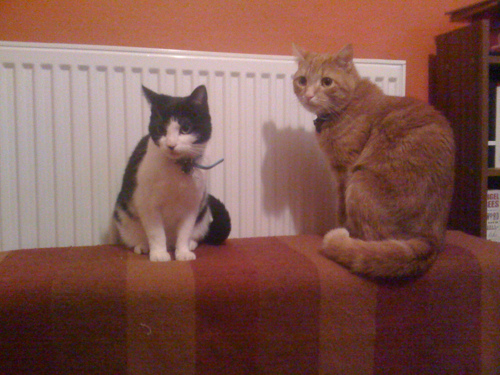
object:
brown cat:
[291, 42, 457, 279]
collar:
[174, 155, 224, 174]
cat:
[113, 84, 230, 263]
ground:
[0, 0, 500, 254]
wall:
[1, 3, 500, 375]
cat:
[112, 42, 456, 278]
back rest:
[0, 40, 407, 253]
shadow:
[259, 120, 334, 233]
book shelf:
[425, 0, 500, 246]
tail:
[201, 193, 230, 244]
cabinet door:
[436, 19, 489, 240]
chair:
[0, 39, 500, 375]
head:
[141, 84, 211, 159]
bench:
[0, 0, 471, 248]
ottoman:
[2, 229, 499, 375]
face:
[149, 100, 211, 159]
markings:
[158, 116, 198, 153]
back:
[0, 39, 407, 252]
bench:
[0, 229, 500, 374]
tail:
[322, 227, 441, 280]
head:
[290, 42, 356, 116]